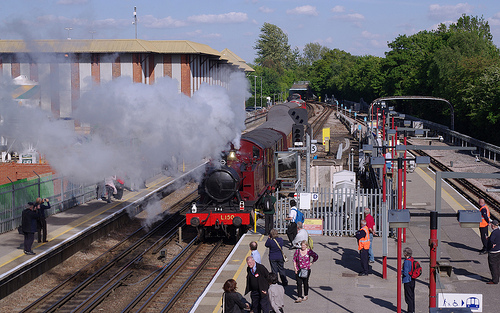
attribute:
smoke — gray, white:
[4, 69, 251, 186]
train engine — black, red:
[181, 129, 287, 235]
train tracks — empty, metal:
[35, 188, 224, 312]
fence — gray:
[275, 186, 388, 235]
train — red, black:
[186, 83, 311, 244]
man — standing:
[354, 221, 378, 275]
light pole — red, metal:
[426, 231, 446, 312]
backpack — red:
[407, 258, 423, 279]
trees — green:
[311, 51, 390, 112]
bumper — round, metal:
[233, 218, 244, 226]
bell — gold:
[225, 151, 239, 163]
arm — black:
[413, 206, 457, 220]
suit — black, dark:
[246, 268, 272, 308]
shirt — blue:
[399, 256, 412, 288]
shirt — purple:
[265, 237, 288, 261]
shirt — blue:
[248, 266, 259, 274]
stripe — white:
[183, 232, 246, 312]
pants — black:
[406, 280, 417, 312]